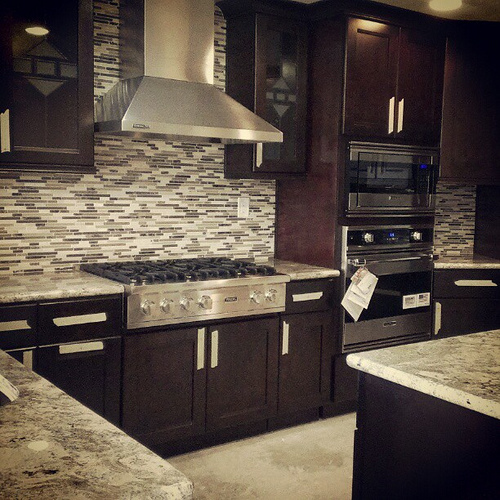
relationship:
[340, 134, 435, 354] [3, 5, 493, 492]
oven in kitchen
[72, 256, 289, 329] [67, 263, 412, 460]
oven in kitchen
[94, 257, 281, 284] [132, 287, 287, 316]
burners in control knobs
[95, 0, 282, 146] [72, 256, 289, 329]
vent in oven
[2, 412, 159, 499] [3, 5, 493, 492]
counter in kitchen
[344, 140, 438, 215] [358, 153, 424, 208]
microwave in glass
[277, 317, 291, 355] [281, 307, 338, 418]
strip in cabinet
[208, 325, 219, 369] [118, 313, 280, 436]
tape in cabinet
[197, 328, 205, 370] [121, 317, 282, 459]
strip in cabinet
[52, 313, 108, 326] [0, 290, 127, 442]
tape in cabinet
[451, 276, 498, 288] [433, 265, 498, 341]
tape in cabinet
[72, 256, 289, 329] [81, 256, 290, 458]
oven of oven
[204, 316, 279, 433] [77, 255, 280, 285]
cabinet under stovetop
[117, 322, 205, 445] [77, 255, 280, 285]
cabinet under stovetop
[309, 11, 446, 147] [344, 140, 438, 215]
cabinet above microwave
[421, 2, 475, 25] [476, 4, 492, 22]
light on ceiling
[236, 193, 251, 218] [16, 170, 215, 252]
electrical pad on wall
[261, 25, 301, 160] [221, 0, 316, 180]
design on cabinet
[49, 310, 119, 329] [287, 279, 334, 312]
tape on a brown drawer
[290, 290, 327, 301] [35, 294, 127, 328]
tape on a drawer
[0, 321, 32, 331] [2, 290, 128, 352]
tape on a drawer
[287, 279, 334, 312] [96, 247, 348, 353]
brown drawer on stove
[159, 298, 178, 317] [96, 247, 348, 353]
knobs on stove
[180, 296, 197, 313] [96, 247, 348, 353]
knobs on stove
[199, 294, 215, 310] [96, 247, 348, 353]
knobs on stove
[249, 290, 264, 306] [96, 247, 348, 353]
knobs on stove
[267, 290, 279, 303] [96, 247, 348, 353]
knobs on stove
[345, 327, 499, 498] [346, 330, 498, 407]
kitchen island with marble countertop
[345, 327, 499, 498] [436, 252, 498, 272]
kitchen island with marble countertop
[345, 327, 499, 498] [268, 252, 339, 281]
kitchen island with marble countertop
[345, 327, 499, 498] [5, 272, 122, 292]
kitchen island with marble countertop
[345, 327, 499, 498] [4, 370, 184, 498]
kitchen island with marble countertop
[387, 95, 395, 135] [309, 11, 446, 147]
tape on cabinet